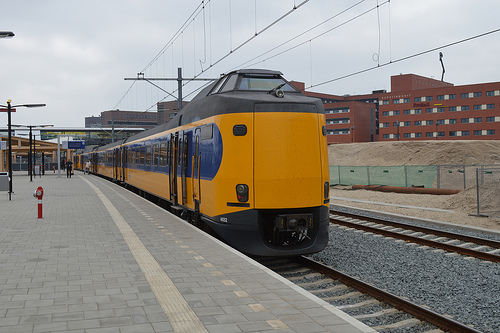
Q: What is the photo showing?
A: It is showing a train station.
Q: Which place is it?
A: It is a train station.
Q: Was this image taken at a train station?
A: Yes, it was taken in a train station.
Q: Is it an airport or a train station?
A: It is a train station.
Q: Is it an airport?
A: No, it is a train station.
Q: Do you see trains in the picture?
A: Yes, there is a train.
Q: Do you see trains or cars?
A: Yes, there is a train.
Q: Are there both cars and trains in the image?
A: No, there is a train but no cars.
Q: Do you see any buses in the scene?
A: No, there are no buses.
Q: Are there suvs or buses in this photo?
A: No, there are no buses or suvs.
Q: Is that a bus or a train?
A: That is a train.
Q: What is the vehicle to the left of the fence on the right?
A: The vehicle is a train.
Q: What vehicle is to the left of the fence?
A: The vehicle is a train.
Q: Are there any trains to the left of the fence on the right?
A: Yes, there is a train to the left of the fence.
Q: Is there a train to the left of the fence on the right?
A: Yes, there is a train to the left of the fence.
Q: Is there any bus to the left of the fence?
A: No, there is a train to the left of the fence.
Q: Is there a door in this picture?
A: Yes, there is a door.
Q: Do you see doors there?
A: Yes, there is a door.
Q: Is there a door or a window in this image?
A: Yes, there is a door.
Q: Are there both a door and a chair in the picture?
A: No, there is a door but no chairs.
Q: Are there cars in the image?
A: No, there are no cars.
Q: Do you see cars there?
A: No, there are no cars.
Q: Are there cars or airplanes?
A: No, there are no cars or airplanes.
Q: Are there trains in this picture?
A: Yes, there is a train.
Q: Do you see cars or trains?
A: Yes, there is a train.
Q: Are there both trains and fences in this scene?
A: Yes, there are both a train and a fence.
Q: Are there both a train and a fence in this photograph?
A: Yes, there are both a train and a fence.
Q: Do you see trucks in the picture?
A: No, there are no trucks.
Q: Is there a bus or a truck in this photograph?
A: No, there are no trucks or buses.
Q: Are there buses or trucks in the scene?
A: No, there are no trucks or buses.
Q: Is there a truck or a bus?
A: No, there are no trucks or buses.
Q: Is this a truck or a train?
A: This is a train.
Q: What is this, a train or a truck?
A: This is a train.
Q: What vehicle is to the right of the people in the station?
A: The vehicle is a train.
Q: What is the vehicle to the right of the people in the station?
A: The vehicle is a train.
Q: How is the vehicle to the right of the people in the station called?
A: The vehicle is a train.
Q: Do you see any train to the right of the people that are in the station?
A: Yes, there is a train to the right of the people.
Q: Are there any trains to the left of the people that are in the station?
A: No, the train is to the right of the people.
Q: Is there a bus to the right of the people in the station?
A: No, there is a train to the right of the people.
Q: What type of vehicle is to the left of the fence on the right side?
A: The vehicle is a train.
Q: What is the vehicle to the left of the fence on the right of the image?
A: The vehicle is a train.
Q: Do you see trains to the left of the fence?
A: Yes, there is a train to the left of the fence.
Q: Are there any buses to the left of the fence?
A: No, there is a train to the left of the fence.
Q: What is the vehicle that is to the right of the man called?
A: The vehicle is a train.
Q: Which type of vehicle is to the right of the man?
A: The vehicle is a train.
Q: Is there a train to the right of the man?
A: Yes, there is a train to the right of the man.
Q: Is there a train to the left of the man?
A: No, the train is to the right of the man.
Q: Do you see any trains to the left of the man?
A: No, the train is to the right of the man.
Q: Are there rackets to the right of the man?
A: No, there is a train to the right of the man.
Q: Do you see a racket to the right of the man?
A: No, there is a train to the right of the man.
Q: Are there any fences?
A: Yes, there is a fence.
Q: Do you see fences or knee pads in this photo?
A: Yes, there is a fence.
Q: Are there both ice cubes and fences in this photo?
A: No, there is a fence but no ice cubes.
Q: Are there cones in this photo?
A: No, there are no cones.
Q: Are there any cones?
A: No, there are no cones.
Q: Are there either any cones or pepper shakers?
A: No, there are no cones or pepper shakers.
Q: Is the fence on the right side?
A: Yes, the fence is on the right of the image.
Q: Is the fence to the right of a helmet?
A: No, the fence is to the right of the train.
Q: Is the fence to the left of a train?
A: No, the fence is to the right of a train.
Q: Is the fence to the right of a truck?
A: No, the fence is to the right of a train.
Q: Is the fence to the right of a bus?
A: No, the fence is to the right of a train.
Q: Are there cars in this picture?
A: No, there are no cars.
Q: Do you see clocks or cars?
A: No, there are no cars or clocks.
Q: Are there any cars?
A: No, there are no cars.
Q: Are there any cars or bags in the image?
A: No, there are no cars or bags.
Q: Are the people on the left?
A: Yes, the people are on the left of the image.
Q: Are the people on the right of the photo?
A: No, the people are on the left of the image.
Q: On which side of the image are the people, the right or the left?
A: The people are on the left of the image.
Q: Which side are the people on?
A: The people are on the left of the image.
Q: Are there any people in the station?
A: Yes, there are people in the station.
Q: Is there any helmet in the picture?
A: No, there are no helmets.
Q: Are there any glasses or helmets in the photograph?
A: No, there are no helmets or glasses.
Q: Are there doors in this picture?
A: Yes, there is a door.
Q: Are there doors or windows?
A: Yes, there is a door.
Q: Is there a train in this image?
A: Yes, there is a train.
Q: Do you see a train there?
A: Yes, there is a train.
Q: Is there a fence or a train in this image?
A: Yes, there is a train.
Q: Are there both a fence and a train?
A: Yes, there are both a train and a fence.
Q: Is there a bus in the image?
A: No, there are no buses.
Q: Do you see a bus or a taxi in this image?
A: No, there are no buses or taxis.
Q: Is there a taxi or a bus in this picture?
A: No, there are no buses or taxis.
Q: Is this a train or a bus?
A: This is a train.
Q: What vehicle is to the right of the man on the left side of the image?
A: The vehicle is a train.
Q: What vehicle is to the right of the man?
A: The vehicle is a train.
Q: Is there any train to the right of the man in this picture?
A: Yes, there is a train to the right of the man.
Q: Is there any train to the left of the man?
A: No, the train is to the right of the man.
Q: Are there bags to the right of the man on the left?
A: No, there is a train to the right of the man.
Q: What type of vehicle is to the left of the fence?
A: The vehicle is a train.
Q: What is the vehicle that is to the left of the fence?
A: The vehicle is a train.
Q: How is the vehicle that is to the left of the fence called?
A: The vehicle is a train.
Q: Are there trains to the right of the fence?
A: No, the train is to the left of the fence.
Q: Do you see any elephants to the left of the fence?
A: No, there is a train to the left of the fence.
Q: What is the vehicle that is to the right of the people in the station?
A: The vehicle is a train.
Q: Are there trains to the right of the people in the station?
A: Yes, there is a train to the right of the people.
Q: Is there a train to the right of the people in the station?
A: Yes, there is a train to the right of the people.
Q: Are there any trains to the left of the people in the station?
A: No, the train is to the right of the people.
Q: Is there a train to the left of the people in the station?
A: No, the train is to the right of the people.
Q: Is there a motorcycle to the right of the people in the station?
A: No, there is a train to the right of the people.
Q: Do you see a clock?
A: No, there are no clocks.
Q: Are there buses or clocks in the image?
A: No, there are no clocks or buses.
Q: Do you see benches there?
A: No, there are no benches.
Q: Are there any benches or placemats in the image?
A: No, there are no benches or placemats.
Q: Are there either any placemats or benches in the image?
A: No, there are no benches or placemats.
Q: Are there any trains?
A: Yes, there is a train.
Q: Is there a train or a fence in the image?
A: Yes, there is a train.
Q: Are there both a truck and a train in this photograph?
A: No, there is a train but no trucks.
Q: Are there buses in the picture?
A: No, there are no buses.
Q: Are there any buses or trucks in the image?
A: No, there are no buses or trucks.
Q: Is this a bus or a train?
A: This is a train.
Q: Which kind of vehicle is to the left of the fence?
A: The vehicle is a train.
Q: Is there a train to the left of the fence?
A: Yes, there is a train to the left of the fence.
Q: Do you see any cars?
A: No, there are no cars.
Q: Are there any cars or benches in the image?
A: No, there are no cars or benches.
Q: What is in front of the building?
A: The train station is in front of the building.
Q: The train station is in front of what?
A: The train station is in front of the building.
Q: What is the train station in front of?
A: The train station is in front of the building.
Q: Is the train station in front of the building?
A: Yes, the train station is in front of the building.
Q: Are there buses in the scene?
A: No, there are no buses.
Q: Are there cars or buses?
A: No, there are no buses or cars.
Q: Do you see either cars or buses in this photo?
A: No, there are no buses or cars.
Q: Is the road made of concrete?
A: Yes, the road is made of concrete.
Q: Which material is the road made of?
A: The road is made of concrete.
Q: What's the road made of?
A: The road is made of concrete.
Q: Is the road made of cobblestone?
A: No, the road is made of concrete.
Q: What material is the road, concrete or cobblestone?
A: The road is made of concrete.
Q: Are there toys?
A: No, there are no toys.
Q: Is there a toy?
A: No, there are no toys.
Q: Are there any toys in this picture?
A: No, there are no toys.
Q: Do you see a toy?
A: No, there are no toys.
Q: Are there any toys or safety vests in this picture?
A: No, there are no toys or safety vests.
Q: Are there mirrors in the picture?
A: No, there are no mirrors.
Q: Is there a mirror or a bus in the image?
A: No, there are no mirrors or buses.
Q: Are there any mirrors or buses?
A: No, there are no mirrors or buses.